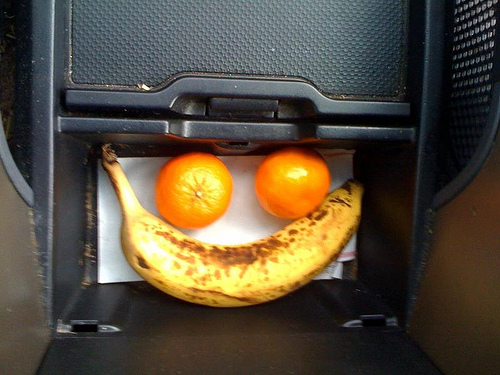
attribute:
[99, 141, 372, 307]
fruits — smiling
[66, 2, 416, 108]
covering — rubberized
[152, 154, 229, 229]
orange — lit, stemmed, shadowed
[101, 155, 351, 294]
paper — white, folded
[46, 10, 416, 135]
compartment — covering, hard, black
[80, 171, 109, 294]
debris — here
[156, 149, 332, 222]
oranges — here, bright, lit, juicy, fresh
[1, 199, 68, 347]
carpetting — blue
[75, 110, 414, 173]
guard — plastic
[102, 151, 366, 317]
banana — yellow, ripe, spotted, browning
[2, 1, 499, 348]
box — black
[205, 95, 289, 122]
handle — black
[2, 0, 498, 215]
plastic — round, holey, circular, diamond textured, curved, rectangular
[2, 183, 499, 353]
wall — smooth, black, brown